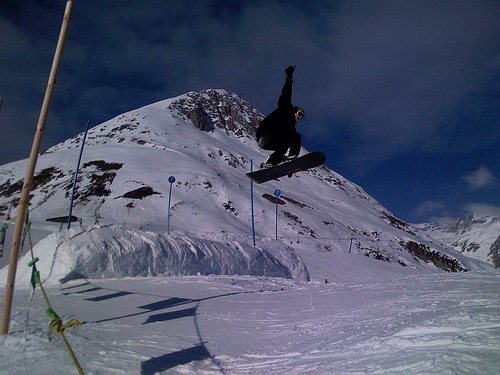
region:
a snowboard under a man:
[244, 149, 327, 184]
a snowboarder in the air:
[252, 57, 312, 165]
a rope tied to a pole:
[18, 202, 96, 373]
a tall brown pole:
[2, 1, 74, 336]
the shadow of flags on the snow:
[58, 262, 223, 373]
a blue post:
[62, 112, 93, 232]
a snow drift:
[28, 227, 302, 281]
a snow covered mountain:
[0, 89, 491, 297]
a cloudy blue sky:
[0, 2, 498, 230]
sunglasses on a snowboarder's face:
[296, 109, 309, 120]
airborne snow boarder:
[194, 48, 329, 193]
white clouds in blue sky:
[80, 15, 127, 60]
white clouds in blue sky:
[87, 63, 111, 78]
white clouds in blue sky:
[130, 26, 171, 48]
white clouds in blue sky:
[103, 65, 133, 85]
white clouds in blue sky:
[151, 6, 191, 37]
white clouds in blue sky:
[351, 36, 391, 90]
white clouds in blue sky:
[336, 112, 414, 149]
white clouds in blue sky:
[383, 23, 460, 85]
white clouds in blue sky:
[321, 38, 398, 98]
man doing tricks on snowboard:
[261, 52, 341, 214]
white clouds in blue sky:
[13, 19, 37, 61]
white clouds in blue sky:
[81, 30, 116, 81]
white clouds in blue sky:
[90, 34, 177, 66]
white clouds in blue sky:
[200, 25, 235, 60]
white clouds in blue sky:
[411, 7, 473, 56]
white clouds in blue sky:
[372, 103, 446, 135]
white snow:
[278, 286, 366, 322]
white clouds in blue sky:
[211, 41, 265, 65]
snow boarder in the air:
[226, 45, 327, 186]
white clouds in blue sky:
[26, 10, 33, 54]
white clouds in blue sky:
[67, 23, 111, 57]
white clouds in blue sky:
[83, 50, 121, 55]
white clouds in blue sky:
[111, 9, 151, 51]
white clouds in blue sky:
[166, 16, 251, 54]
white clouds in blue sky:
[334, 16, 381, 84]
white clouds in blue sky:
[414, 40, 464, 111]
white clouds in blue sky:
[349, 124, 430, 172]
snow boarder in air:
[234, 69, 321, 183]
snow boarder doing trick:
[230, 50, 340, 215]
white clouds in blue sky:
[4, 21, 53, 74]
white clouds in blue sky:
[399, 46, 418, 61]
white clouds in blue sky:
[326, 116, 379, 157]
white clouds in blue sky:
[110, 18, 173, 70]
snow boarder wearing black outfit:
[226, 57, 327, 198]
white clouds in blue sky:
[158, 19, 208, 58]